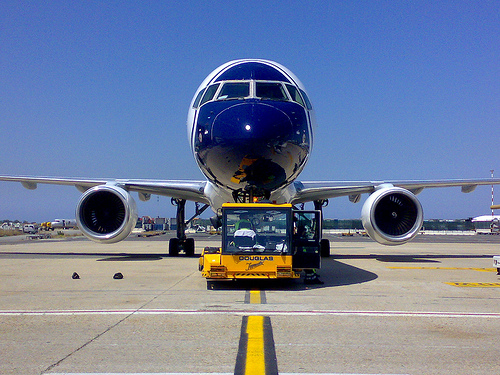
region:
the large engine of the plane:
[73, 179, 133, 239]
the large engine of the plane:
[362, 185, 422, 245]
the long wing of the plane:
[2, 171, 207, 203]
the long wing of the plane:
[300, 174, 497, 202]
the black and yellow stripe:
[233, 288, 280, 374]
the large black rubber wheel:
[168, 236, 180, 255]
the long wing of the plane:
[185, 236, 195, 255]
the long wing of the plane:
[317, 237, 330, 256]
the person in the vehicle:
[232, 219, 258, 247]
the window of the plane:
[215, 79, 253, 100]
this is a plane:
[168, 82, 399, 286]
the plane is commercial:
[203, 159, 249, 221]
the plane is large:
[196, 94, 256, 149]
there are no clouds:
[120, 98, 129, 115]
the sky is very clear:
[95, 105, 123, 152]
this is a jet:
[63, 176, 130, 245]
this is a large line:
[258, 315, 268, 353]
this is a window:
[205, 26, 315, 154]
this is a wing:
[342, 171, 428, 191]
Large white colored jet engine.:
[364, 187, 426, 247]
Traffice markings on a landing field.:
[229, 298, 283, 373]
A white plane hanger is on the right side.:
[468, 214, 498, 239]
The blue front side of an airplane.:
[186, 54, 316, 195]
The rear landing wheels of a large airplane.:
[164, 237, 198, 259]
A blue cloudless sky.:
[16, 7, 495, 45]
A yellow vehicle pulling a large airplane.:
[198, 202, 334, 288]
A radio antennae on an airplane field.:
[488, 159, 498, 216]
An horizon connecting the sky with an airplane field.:
[2, 216, 498, 241]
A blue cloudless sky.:
[332, 28, 482, 163]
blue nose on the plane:
[199, 99, 309, 184]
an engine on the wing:
[75, 185, 134, 240]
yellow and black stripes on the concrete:
[234, 311, 280, 373]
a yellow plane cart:
[198, 203, 325, 283]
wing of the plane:
[302, 172, 497, 200]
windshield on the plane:
[188, 82, 310, 113]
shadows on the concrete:
[0, 241, 163, 264]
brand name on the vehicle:
[234, 254, 275, 264]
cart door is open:
[282, 210, 327, 272]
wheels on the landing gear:
[166, 232, 198, 256]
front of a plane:
[175, 58, 328, 203]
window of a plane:
[196, 65, 301, 111]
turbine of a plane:
[70, 187, 133, 235]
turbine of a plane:
[360, 171, 439, 236]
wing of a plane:
[0, 148, 82, 197]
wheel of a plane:
[165, 229, 202, 262]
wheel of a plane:
[312, 231, 339, 254]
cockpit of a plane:
[187, 28, 307, 184]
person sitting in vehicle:
[227, 214, 265, 262]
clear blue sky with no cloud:
[357, 43, 464, 116]